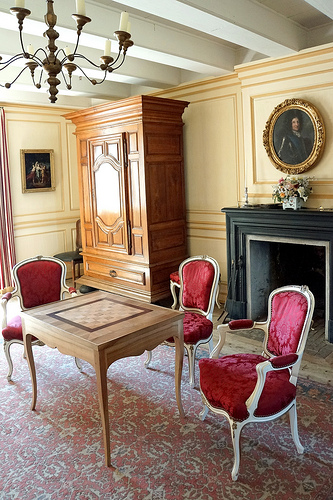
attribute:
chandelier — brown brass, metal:
[12, 10, 122, 76]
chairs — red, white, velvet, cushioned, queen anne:
[34, 261, 315, 390]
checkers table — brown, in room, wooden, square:
[26, 304, 179, 436]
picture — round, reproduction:
[256, 94, 333, 177]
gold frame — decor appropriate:
[282, 94, 309, 110]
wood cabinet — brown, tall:
[72, 109, 178, 287]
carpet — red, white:
[52, 438, 100, 494]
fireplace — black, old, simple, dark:
[225, 207, 328, 323]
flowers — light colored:
[280, 186, 301, 194]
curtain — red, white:
[4, 149, 20, 257]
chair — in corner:
[15, 264, 65, 335]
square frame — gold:
[13, 138, 71, 200]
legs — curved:
[19, 340, 201, 460]